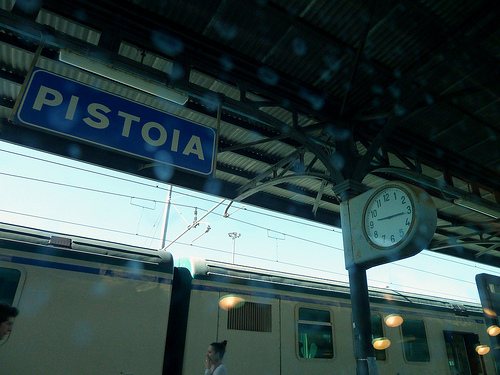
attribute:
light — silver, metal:
[224, 230, 245, 269]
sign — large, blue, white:
[14, 54, 277, 207]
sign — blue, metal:
[15, 51, 235, 195]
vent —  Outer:
[225, 297, 274, 335]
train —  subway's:
[0, 222, 498, 374]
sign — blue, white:
[18, 85, 215, 183]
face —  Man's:
[307, 329, 335, 351]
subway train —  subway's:
[0, 213, 498, 371]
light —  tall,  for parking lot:
[220, 226, 245, 263]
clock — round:
[336, 177, 436, 274]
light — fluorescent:
[61, 53, 188, 108]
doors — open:
[440, 331, 489, 373]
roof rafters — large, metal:
[3, 2, 498, 262]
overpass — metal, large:
[2, 2, 497, 268]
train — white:
[129, 234, 499, 374]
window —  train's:
[279, 297, 339, 358]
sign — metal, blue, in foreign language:
[12, 66, 217, 179]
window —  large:
[146, 102, 324, 281]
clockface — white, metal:
[364, 186, 413, 246]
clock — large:
[362, 186, 416, 245]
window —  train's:
[300, 311, 333, 359]